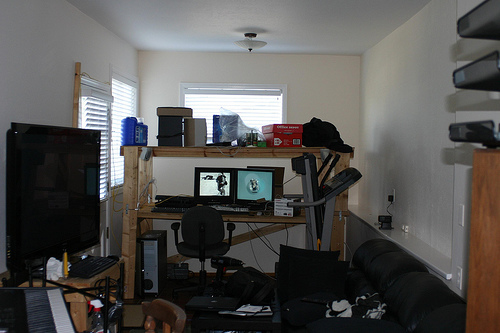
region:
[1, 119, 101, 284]
a large flat screen TV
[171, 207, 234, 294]
a rolling office chair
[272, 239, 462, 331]
a dark cushioned couch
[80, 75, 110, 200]
a set of white venetian blinds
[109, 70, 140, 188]
a set of white venetian blinds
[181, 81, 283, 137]
a set of white venetian blinds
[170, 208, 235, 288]
An office chair near a desk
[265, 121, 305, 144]
A red box on top of a shelf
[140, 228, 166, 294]
A computer tower under a desk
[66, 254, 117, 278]
A black keyboard on a table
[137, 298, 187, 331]
The top of a wooden chair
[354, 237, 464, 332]
Brown cusions on top of a couch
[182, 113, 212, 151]
clutter in small room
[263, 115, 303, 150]
clutter in small room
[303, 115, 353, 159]
clutter in small room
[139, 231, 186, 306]
clutter in small room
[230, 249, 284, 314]
clutter in small room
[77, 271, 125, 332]
clutter in small room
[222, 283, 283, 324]
clutter in small room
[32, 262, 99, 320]
clutter in small room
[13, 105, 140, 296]
a black television on shelf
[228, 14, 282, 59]
a white light fixture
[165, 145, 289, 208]
two computer monitors on desk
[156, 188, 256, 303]
this is a chair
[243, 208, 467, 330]
this is a sofa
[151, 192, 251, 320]
the chair is black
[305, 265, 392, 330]
items on the sofa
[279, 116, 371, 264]
folded up work out equipment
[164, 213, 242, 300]
a cushioned desk chair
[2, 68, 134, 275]
a flat screen tv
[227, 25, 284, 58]
a light in the ceiling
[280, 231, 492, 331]
a large black sofa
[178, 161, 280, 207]
two computer screens turned on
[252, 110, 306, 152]
a red box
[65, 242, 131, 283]
a computer keyboard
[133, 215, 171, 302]
a computer tower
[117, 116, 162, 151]
the book is blue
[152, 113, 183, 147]
the container is black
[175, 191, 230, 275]
the chair is black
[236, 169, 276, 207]
the screen is on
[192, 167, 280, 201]
monitors on the desk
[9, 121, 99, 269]
the tv is off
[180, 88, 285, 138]
the blinds are open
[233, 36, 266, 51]
light on the ceiling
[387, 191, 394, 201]
the plug is black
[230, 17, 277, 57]
A light fixture on the ceiling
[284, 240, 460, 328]
A large black couch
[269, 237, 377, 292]
Black pillows on a black couch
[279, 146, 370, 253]
a grey exercise machine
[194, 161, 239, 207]
A monitor on a desk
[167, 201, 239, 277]
a computer chair in front of the desk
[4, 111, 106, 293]
an HDTV on a Table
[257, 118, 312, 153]
The red box on the shelf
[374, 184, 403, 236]
an apparatus plugged into the wall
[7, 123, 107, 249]
big television on the right side of the room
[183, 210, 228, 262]
Black and gray desk chair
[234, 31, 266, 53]
small white ceiling lamp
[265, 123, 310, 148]
red rectangular box on the cabinet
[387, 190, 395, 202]
black wall charger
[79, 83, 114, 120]
white window blinds left